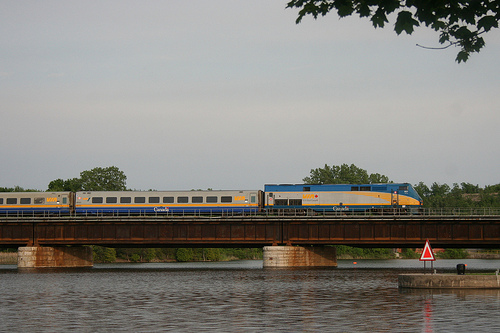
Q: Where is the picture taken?
A: A bridge.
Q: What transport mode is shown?
A: A train.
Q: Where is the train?
A: The tracks.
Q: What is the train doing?
A: Crossing the bridge.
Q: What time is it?
A: Afternoon.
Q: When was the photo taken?
A: During the daytime.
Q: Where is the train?
A: On the tracks.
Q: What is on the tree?
A: Leaves.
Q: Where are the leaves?
A: On the tree.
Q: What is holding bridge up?
A: Bricks.